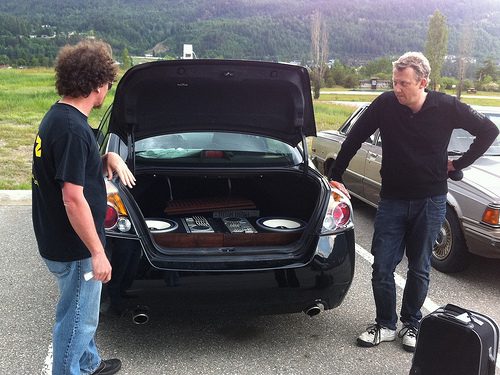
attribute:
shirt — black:
[314, 89, 499, 181]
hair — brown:
[51, 38, 122, 100]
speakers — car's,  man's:
[137, 200, 305, 245]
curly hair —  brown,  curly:
[52, 36, 119, 99]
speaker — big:
[220, 215, 311, 249]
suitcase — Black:
[386, 287, 497, 370]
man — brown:
[6, 32, 166, 373]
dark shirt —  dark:
[322, 85, 499, 199]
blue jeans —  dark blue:
[372, 195, 447, 325]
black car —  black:
[99, 52, 359, 323]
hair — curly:
[55, 37, 118, 98]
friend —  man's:
[27, 39, 134, 372]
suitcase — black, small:
[404, 300, 496, 372]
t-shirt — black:
[32, 98, 108, 262]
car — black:
[65, 65, 372, 335]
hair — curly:
[50, 41, 120, 91]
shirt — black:
[30, 99, 144, 275]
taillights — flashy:
[315, 186, 375, 246]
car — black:
[86, 33, 400, 333]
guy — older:
[339, 39, 488, 366]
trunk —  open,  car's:
[118, 58, 325, 265]